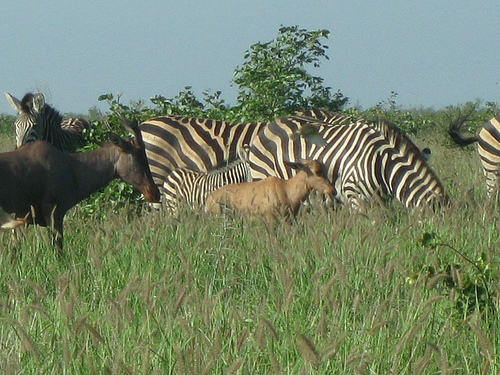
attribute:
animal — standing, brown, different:
[3, 120, 160, 264]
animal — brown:
[204, 160, 335, 222]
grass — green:
[2, 137, 500, 374]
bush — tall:
[237, 30, 344, 112]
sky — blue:
[2, 0, 498, 122]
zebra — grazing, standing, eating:
[247, 115, 449, 216]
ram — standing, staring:
[1, 121, 166, 254]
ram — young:
[202, 162, 337, 222]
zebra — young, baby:
[163, 158, 255, 218]